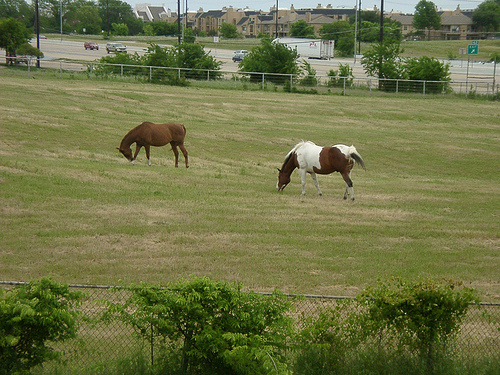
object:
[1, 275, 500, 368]
fences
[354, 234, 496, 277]
grass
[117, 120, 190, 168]
brown horse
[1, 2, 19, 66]
tree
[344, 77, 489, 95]
far fence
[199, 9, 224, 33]
houses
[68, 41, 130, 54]
traffic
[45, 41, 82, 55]
street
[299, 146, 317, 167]
horse with white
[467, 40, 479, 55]
sign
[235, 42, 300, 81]
bushes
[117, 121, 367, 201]
two horses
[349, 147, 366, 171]
tail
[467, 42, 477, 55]
exit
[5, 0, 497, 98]
background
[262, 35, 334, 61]
truck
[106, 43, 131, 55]
pickup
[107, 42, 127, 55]
cap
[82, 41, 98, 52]
car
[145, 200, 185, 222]
brown sections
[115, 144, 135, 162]
grazing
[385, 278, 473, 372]
plants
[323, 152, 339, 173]
brown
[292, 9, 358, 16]
roofs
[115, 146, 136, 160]
head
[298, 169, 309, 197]
white legs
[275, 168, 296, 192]
head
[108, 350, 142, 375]
green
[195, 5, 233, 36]
suburb